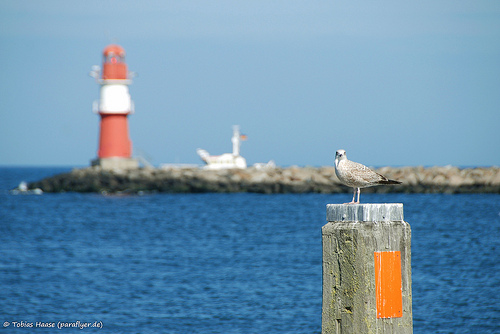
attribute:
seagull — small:
[324, 140, 396, 202]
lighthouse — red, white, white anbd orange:
[73, 35, 142, 165]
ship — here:
[184, 96, 258, 175]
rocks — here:
[50, 159, 279, 206]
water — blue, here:
[115, 216, 286, 266]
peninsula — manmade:
[40, 153, 496, 197]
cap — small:
[330, 195, 410, 224]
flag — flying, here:
[235, 125, 257, 145]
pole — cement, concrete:
[319, 230, 418, 301]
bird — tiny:
[315, 137, 413, 214]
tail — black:
[378, 173, 412, 195]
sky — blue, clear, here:
[180, 21, 459, 129]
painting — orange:
[370, 240, 406, 286]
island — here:
[34, 129, 476, 219]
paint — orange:
[371, 242, 396, 265]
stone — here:
[26, 166, 98, 189]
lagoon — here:
[16, 118, 58, 226]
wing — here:
[355, 159, 383, 188]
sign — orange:
[373, 250, 405, 319]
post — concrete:
[324, 199, 412, 332]